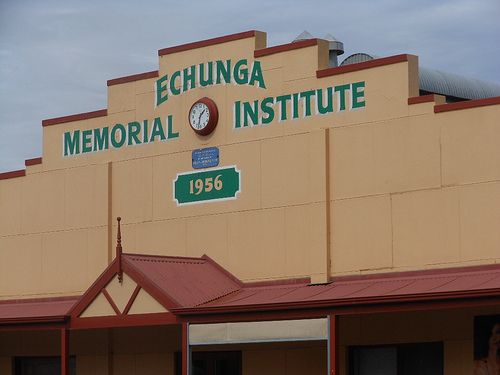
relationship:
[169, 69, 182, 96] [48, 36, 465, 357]
c on front of building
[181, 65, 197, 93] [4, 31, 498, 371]
h on front of building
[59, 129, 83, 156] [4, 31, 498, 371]
letter front of building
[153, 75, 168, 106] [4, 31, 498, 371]
e front of building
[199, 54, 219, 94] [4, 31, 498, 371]
'u' on front of building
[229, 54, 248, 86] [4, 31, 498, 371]
letter on front of building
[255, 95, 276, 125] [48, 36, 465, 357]
s on front of building